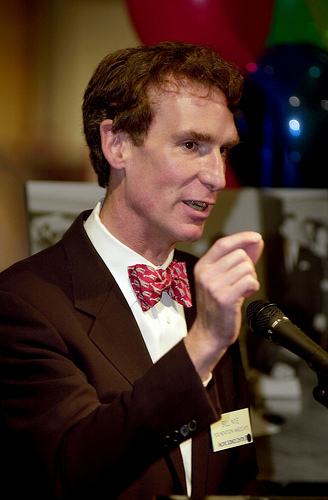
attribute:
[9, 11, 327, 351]
person — standing up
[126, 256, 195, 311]
bowtie — red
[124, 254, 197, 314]
tie — red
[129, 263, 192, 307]
bow tie — red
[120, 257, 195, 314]
bow tie — red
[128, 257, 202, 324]
bow tie — red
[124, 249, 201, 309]
bow tie —  grey bow, red 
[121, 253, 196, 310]
tie — bow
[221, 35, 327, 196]
balloon — blue, helium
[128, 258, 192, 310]
bow tie — red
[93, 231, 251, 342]
tie — red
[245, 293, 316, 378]
device — black microphone